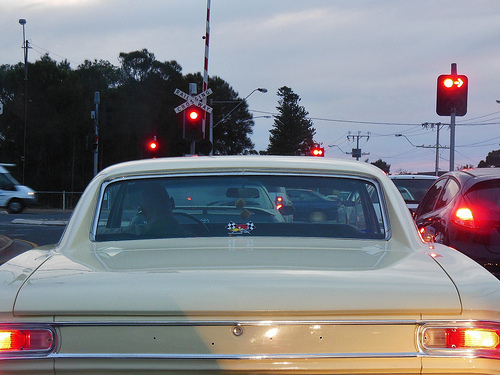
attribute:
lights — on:
[185, 99, 200, 125]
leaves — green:
[1, 52, 313, 164]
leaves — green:
[111, 82, 141, 119]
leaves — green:
[14, 65, 143, 119]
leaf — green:
[273, 107, 283, 112]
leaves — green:
[282, 99, 306, 119]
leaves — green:
[267, 117, 287, 131]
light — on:
[3, 322, 498, 356]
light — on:
[443, 168, 475, 242]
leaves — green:
[0, 49, 253, 205]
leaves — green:
[3, 48, 318, 177]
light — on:
[144, 133, 154, 152]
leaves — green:
[46, 55, 103, 82]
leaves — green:
[9, 70, 77, 151]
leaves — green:
[36, 85, 75, 134]